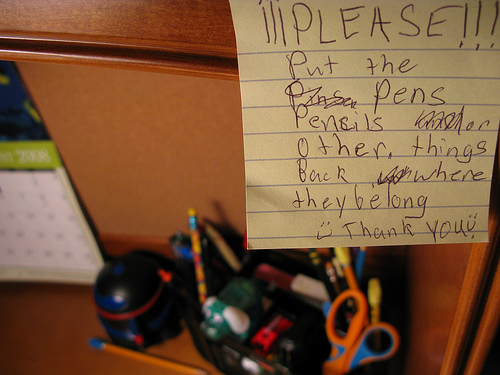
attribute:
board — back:
[42, 66, 229, 251]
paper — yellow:
[227, 17, 485, 266]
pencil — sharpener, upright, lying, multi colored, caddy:
[115, 313, 186, 375]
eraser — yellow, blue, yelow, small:
[359, 277, 388, 307]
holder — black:
[282, 309, 405, 374]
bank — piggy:
[73, 228, 206, 359]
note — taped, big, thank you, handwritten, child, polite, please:
[193, 10, 491, 267]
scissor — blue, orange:
[337, 269, 425, 370]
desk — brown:
[37, 277, 112, 368]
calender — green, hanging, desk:
[5, 33, 148, 273]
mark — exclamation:
[234, 6, 289, 74]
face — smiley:
[319, 211, 338, 245]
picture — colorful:
[2, 58, 85, 150]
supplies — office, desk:
[154, 205, 399, 348]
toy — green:
[81, 238, 151, 329]